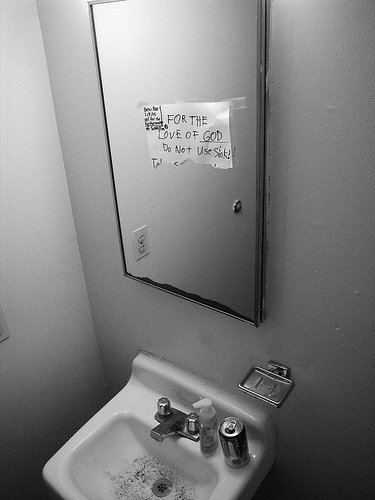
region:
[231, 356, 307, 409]
soap dish hanging on the wall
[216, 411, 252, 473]
drink can sitting on the sink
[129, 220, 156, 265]
a plug socket reflected in the mirror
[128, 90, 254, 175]
a note hanging on the mirror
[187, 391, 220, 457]
Hand soap sitting on the sink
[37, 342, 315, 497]
A white bathroom sink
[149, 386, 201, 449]
metallic faucet on a bathroom sink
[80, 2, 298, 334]
A mirror hanging on the wall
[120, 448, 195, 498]
Debris inside the sink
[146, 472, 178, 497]
A drain in the sink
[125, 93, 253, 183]
Warning note on mirror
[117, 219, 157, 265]
Outlet reflected in mirror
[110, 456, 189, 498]
Sink has black filth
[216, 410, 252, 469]
Silver soda can on sink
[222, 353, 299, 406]
Soap dish attached to wall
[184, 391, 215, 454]
Soap dispenser on sink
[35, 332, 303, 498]
Sink attached to wall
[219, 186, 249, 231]
Door stopper reflected in mirror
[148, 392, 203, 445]
Faucet is older model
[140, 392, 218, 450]
Faucet is silver in color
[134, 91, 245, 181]
sign attached to mirror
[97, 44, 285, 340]
large mirror with a sign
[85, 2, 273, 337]
large mirror attached to the wall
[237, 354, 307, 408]
empty soap holder above sink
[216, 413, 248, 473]
soda can on the side of the sink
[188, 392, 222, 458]
hand soap bottle next to soda can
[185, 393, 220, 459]
hand soap bottle on top of sink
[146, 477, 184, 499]
plug hole at the bottom of the sink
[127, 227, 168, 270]
reflection of outlets in the mirror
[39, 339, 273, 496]
white sink against the wall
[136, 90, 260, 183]
paper sign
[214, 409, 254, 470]
Can on sink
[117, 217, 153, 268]
light switch in mirror.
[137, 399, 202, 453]
faucet on sink.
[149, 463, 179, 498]
drain in sink.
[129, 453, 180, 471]
section of debris in sink.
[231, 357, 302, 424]
metal soap dish.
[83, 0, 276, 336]
Large bathroom mirror placed over a sink.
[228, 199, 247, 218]
metal object on bathroom wall.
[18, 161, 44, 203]
section of a bathroom wall.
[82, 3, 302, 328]
a medicine cabinet with a mirror on it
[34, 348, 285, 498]
a dirty white bathroom sink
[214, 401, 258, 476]
an open can of soda sitting on the sink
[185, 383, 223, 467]
a clear bottle of soap next to a soda can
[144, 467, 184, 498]
a silver drain cover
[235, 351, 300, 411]
an empty silver soap dish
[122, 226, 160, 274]
a reflection of a plug in on the wall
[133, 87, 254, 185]
a half piece of paper taped to bathroom mirror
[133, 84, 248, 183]
paper stating not to use the sink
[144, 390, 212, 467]
silver knobs on the sink